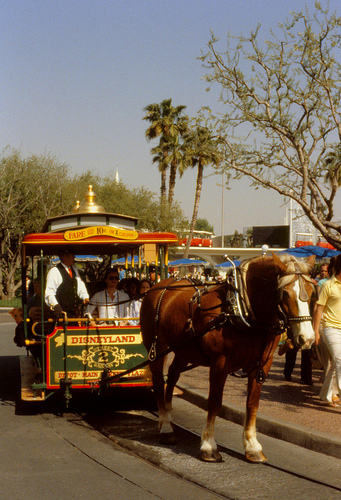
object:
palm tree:
[141, 99, 199, 211]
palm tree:
[176, 126, 224, 276]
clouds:
[11, 16, 77, 90]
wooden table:
[166, 244, 285, 327]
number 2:
[98, 351, 109, 364]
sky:
[4, 2, 337, 233]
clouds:
[235, 196, 283, 229]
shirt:
[316, 277, 340, 330]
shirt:
[84, 288, 129, 320]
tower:
[115, 166, 121, 187]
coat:
[54, 263, 83, 317]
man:
[44, 247, 89, 325]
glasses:
[107, 276, 120, 280]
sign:
[46, 324, 153, 385]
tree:
[1, 153, 52, 304]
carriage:
[19, 183, 308, 452]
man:
[84, 268, 130, 327]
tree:
[151, 135, 188, 215]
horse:
[139, 251, 316, 464]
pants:
[282, 351, 313, 377]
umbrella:
[167, 258, 207, 275]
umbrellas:
[215, 259, 242, 272]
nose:
[296, 331, 317, 347]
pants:
[319, 326, 341, 403]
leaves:
[26, 166, 64, 203]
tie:
[68, 268, 73, 278]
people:
[126, 274, 139, 300]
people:
[313, 255, 341, 408]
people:
[129, 279, 152, 325]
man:
[314, 263, 330, 285]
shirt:
[317, 277, 330, 287]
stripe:
[292, 281, 315, 340]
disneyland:
[67, 335, 141, 346]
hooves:
[201, 426, 224, 464]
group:
[140, 91, 216, 226]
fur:
[150, 282, 223, 340]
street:
[0, 389, 339, 496]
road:
[0, 321, 313, 498]